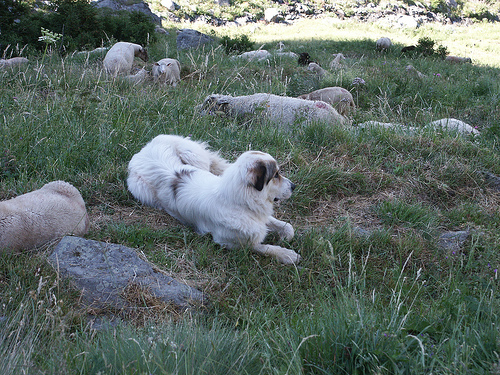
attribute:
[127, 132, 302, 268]
dog — brown, white, working, sheep dog, mostly white, tan black, laying down, alert, black, furry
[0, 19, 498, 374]
grass — tall, long, shady, green, shaded, dry, a field, overgrown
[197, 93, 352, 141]
sheep — laying down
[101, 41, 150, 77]
sheep — standing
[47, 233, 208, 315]
rock — large, flat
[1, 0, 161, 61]
bushes — short, green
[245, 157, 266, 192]
ears — brown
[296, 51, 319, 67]
sheep — black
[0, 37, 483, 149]
group of sheep — laying down, wandering arounf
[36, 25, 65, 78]
plant — tall, flowering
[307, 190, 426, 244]
patch of grass — dry